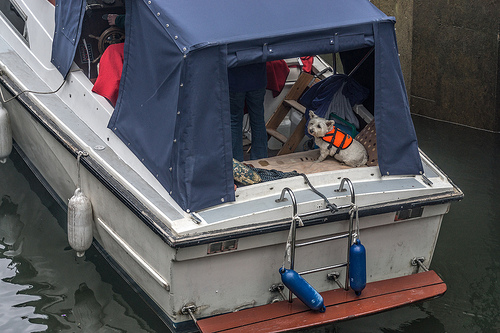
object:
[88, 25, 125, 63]
navigation wheel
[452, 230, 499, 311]
grey water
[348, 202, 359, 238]
rope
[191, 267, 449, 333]
plank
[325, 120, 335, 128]
ear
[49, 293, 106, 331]
calm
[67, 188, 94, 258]
container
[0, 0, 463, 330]
boat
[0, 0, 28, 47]
glass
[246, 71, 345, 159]
ladder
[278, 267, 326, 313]
tank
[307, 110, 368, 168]
dog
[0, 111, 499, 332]
water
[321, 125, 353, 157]
jacket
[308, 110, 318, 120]
ear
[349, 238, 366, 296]
buoy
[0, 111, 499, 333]
reflections